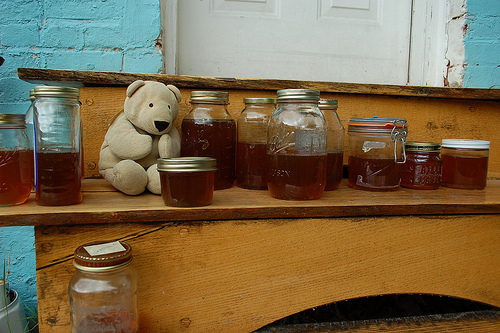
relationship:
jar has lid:
[0, 109, 35, 210] [0, 110, 28, 129]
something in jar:
[1, 149, 36, 208] [0, 109, 35, 210]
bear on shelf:
[97, 79, 182, 195] [0, 178, 498, 228]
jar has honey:
[31, 84, 84, 208] [35, 150, 83, 207]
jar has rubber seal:
[345, 115, 409, 192] [346, 120, 409, 131]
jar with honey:
[179, 87, 236, 194] [179, 114, 237, 193]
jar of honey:
[235, 97, 279, 190] [235, 139, 273, 190]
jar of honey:
[264, 86, 329, 201] [264, 151, 328, 202]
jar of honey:
[317, 95, 347, 193] [325, 150, 344, 193]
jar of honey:
[31, 84, 84, 208] [35, 150, 83, 207]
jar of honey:
[0, 109, 35, 210] [1, 149, 36, 208]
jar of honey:
[440, 137, 491, 191] [441, 153, 491, 191]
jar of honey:
[345, 115, 409, 192] [348, 153, 403, 191]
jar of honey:
[156, 155, 218, 210] [159, 170, 217, 207]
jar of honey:
[401, 141, 443, 192] [402, 153, 444, 193]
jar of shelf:
[440, 137, 491, 191] [0, 178, 498, 228]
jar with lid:
[67, 238, 139, 332] [73, 238, 134, 272]